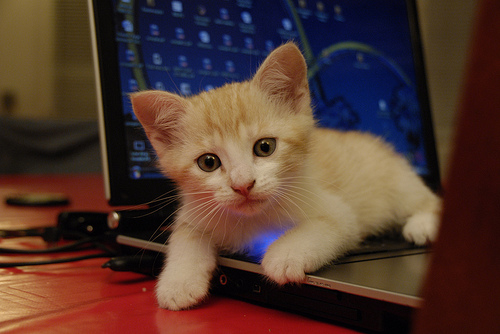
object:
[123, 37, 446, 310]
cat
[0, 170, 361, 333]
table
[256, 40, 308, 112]
cat ears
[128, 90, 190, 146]
cat ears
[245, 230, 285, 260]
light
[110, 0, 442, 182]
screen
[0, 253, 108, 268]
cords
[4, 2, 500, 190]
background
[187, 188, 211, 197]
kittys whiskers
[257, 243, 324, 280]
cat's paw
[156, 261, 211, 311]
paw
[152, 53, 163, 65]
icons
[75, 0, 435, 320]
computer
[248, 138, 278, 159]
eye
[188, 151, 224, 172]
eye